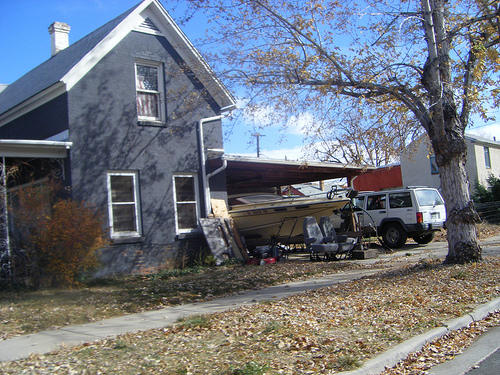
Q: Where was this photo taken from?
A: The street.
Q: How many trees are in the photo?
A: One.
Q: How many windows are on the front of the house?
A: Three.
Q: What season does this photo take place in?
A: Fall.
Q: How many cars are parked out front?
A: One.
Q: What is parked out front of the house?
A: A boat and a truck.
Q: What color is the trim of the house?
A: White.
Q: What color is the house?
A: Blue.